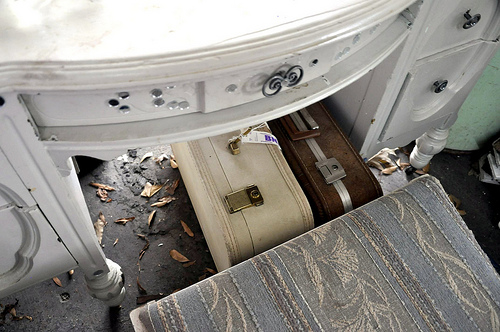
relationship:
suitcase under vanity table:
[191, 146, 302, 228] [14, 11, 462, 121]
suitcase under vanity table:
[299, 121, 356, 200] [14, 11, 462, 121]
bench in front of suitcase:
[228, 248, 493, 329] [191, 146, 302, 228]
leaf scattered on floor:
[171, 248, 191, 264] [123, 242, 136, 268]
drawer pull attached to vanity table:
[438, 75, 449, 94] [14, 11, 462, 121]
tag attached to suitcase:
[250, 130, 276, 145] [191, 146, 302, 228]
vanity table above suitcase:
[14, 11, 462, 121] [191, 146, 302, 228]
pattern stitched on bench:
[312, 249, 365, 314] [228, 248, 493, 329]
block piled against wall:
[478, 154, 493, 185] [471, 78, 497, 153]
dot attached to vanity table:
[108, 99, 120, 107] [14, 11, 462, 121]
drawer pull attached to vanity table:
[465, 12, 484, 29] [14, 11, 462, 121]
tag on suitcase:
[250, 130, 276, 145] [191, 146, 302, 228]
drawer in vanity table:
[383, 47, 481, 142] [14, 11, 462, 121]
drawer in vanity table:
[64, 66, 315, 122] [14, 11, 462, 121]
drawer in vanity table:
[411, 1, 499, 55] [14, 11, 462, 121]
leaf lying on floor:
[140, 183, 155, 196] [123, 242, 136, 268]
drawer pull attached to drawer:
[438, 75, 449, 94] [383, 47, 481, 142]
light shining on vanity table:
[13, 8, 48, 30] [14, 11, 462, 121]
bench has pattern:
[228, 248, 493, 329] [312, 249, 365, 314]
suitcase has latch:
[191, 146, 302, 228] [228, 189, 259, 204]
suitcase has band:
[299, 121, 356, 200] [310, 140, 323, 157]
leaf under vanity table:
[96, 215, 105, 235] [14, 11, 462, 121]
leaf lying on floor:
[171, 248, 191, 264] [123, 242, 136, 268]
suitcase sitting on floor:
[191, 146, 302, 228] [123, 242, 136, 268]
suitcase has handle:
[299, 121, 356, 200] [285, 120, 297, 137]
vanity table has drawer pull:
[14, 11, 462, 121] [265, 70, 309, 91]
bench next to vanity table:
[228, 248, 493, 329] [14, 11, 462, 121]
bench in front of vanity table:
[228, 248, 493, 329] [14, 11, 462, 121]